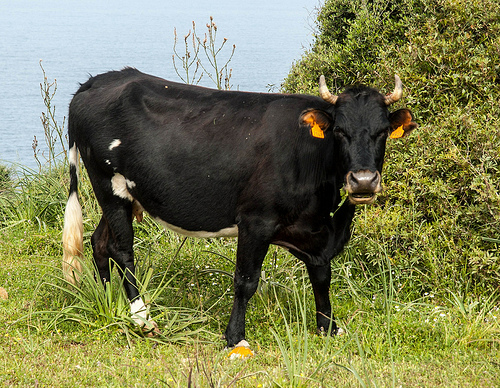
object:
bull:
[59, 64, 417, 349]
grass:
[0, 161, 499, 387]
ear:
[297, 103, 331, 139]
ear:
[389, 105, 416, 141]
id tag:
[310, 121, 325, 138]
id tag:
[387, 124, 407, 139]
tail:
[60, 117, 86, 284]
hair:
[60, 192, 84, 293]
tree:
[272, 0, 499, 300]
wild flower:
[189, 283, 195, 288]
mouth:
[348, 192, 374, 203]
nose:
[348, 172, 379, 186]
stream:
[0, 0, 323, 202]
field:
[0, 166, 500, 387]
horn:
[383, 73, 403, 106]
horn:
[318, 74, 338, 105]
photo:
[0, 0, 500, 388]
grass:
[329, 188, 351, 217]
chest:
[267, 135, 357, 264]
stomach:
[132, 178, 241, 238]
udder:
[130, 201, 143, 222]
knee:
[234, 273, 258, 297]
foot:
[127, 299, 162, 336]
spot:
[127, 299, 154, 331]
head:
[297, 73, 417, 206]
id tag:
[224, 345, 253, 357]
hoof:
[223, 339, 257, 362]